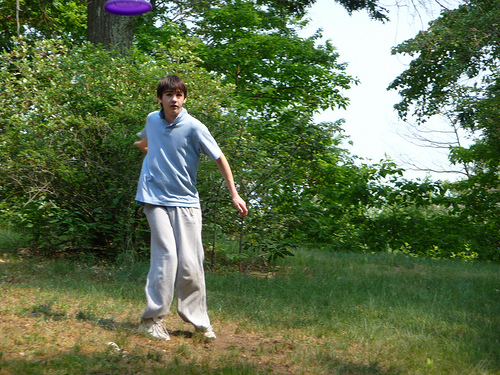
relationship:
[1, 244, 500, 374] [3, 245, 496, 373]
field has grass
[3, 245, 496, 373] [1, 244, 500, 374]
grass in field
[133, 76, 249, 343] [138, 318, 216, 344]
boy wearing shoes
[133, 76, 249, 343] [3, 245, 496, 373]
boy standing on grass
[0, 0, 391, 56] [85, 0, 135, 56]
tree has trunk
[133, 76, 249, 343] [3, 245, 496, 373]
boy on top of grass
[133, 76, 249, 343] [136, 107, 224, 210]
boy wearing t-shirt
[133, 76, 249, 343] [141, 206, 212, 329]
boy wearing pants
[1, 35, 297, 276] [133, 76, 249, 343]
bush behind boy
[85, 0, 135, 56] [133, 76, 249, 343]
trunk behind boy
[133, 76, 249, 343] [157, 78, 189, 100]
boy has hair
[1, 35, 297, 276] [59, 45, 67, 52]
bush has flower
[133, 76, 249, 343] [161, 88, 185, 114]
boy has face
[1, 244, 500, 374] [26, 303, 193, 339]
field has shadow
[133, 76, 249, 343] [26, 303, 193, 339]
boy has shadow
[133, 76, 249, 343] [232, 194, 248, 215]
boy has hand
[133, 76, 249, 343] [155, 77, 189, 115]
boy has head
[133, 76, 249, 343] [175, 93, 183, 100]
boy has eye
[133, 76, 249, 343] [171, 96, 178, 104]
boy has nose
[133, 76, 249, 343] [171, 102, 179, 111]
boy has mouth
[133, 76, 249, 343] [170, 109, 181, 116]
boy has chin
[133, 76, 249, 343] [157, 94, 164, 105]
boy has ear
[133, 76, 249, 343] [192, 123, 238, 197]
boy has arm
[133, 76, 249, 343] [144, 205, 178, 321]
boy has leg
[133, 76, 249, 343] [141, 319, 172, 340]
boy has shoe